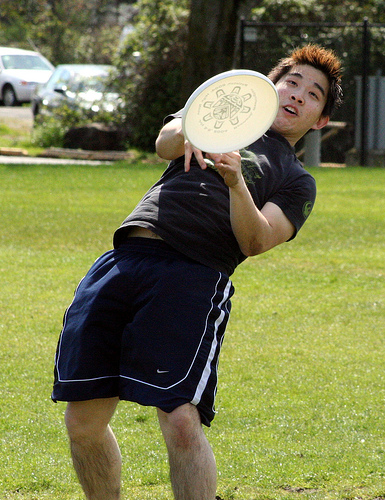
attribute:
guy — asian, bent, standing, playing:
[63, 43, 340, 498]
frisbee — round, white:
[185, 68, 280, 158]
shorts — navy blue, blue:
[53, 236, 236, 426]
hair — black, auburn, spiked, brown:
[265, 43, 345, 117]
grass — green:
[3, 162, 380, 498]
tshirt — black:
[111, 104, 319, 279]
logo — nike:
[155, 366, 170, 377]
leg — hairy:
[160, 402, 218, 500]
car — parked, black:
[31, 64, 129, 129]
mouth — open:
[282, 101, 301, 119]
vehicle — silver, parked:
[1, 48, 57, 113]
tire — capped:
[1, 85, 16, 108]